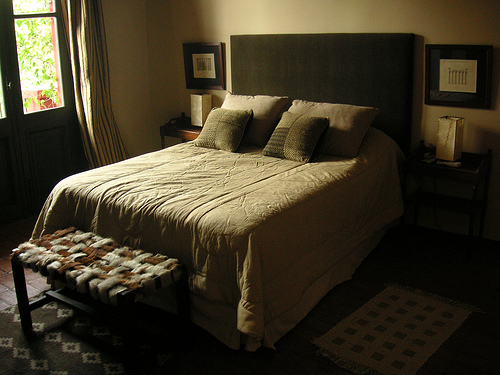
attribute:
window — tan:
[12, 0, 66, 117]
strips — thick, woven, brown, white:
[68, 240, 160, 291]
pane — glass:
[12, 14, 72, 115]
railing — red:
[50, 2, 64, 97]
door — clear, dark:
[1, 2, 86, 252]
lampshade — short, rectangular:
[434, 114, 482, 163]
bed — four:
[54, 74, 440, 329]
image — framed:
[437, 56, 477, 92]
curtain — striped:
[63, 15, 127, 143]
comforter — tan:
[49, 129, 385, 314]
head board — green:
[225, 31, 420, 158]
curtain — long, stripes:
[61, 0, 131, 154]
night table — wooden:
[112, 94, 243, 148]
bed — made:
[30, 32, 424, 351]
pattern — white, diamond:
[43, 324, 97, 361]